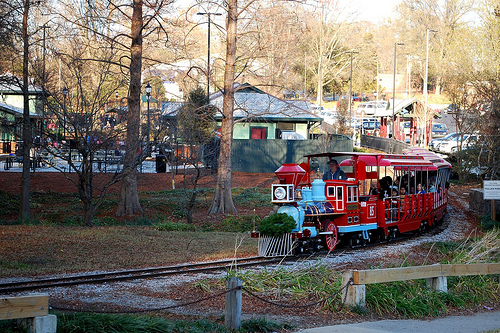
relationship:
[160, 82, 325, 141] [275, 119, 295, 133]
house has window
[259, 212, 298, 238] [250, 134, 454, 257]
wreath on train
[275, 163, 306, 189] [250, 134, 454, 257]
smoke stack on train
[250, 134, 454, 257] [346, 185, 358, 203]
train has window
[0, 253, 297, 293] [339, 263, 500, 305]
tracks has fence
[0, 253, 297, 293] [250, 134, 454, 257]
tracks for train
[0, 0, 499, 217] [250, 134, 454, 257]
tree behind train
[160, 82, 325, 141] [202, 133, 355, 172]
house behind fence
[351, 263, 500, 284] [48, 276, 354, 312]
railing has chain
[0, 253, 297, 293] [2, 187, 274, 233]
tracks by grass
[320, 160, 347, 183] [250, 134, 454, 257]
guard on train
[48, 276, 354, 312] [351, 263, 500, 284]
chain by railing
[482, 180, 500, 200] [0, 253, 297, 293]
sign by tracks